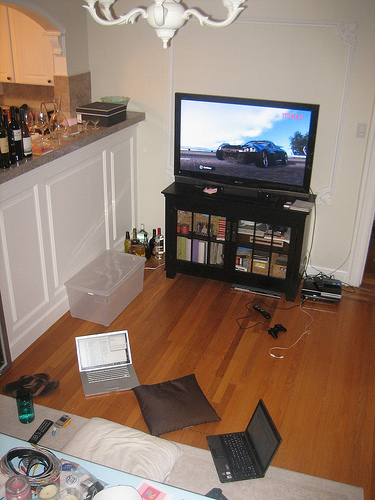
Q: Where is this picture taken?
A: The living room.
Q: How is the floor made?
A: Of wood.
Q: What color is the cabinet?
A: White.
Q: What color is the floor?
A: Oak.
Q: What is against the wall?
A: A television.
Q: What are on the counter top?
A: Wine bottles.